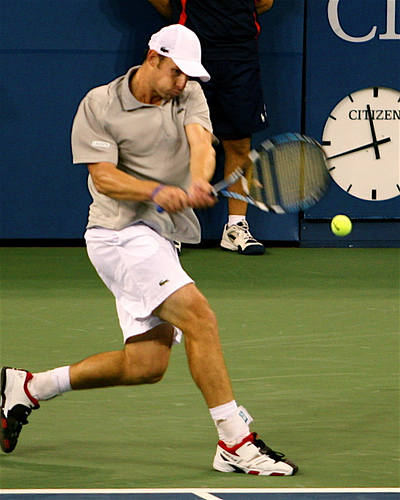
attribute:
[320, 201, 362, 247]
tennis ball — bright, yellow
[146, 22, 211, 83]
cap — white, baseball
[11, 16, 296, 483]
man — wearing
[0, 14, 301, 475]
player — tennis, hitting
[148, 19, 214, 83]
hat — white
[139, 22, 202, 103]
player's head — tennis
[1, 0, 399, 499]
photo — taken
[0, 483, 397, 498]
white line — long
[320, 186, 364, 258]
ball — green, tennis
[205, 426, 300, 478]
shoes — white, red, black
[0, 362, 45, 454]
shoes — white, red, black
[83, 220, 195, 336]
shorts — white, Nike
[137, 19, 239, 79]
hat — white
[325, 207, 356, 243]
ball — small, green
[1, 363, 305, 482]
tennis shoes — red, white, black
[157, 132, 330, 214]
racket — white, black, blue, tennis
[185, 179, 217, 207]
hand — man's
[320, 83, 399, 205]
clock — giant, Citizen, black, white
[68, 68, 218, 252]
shirt — gray